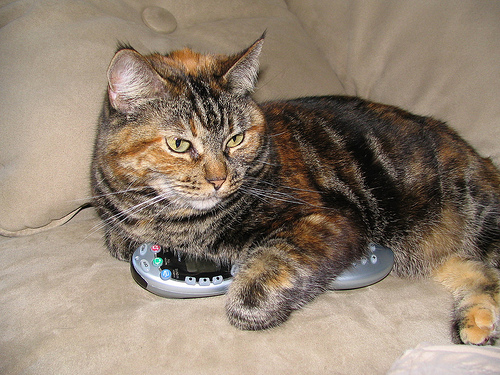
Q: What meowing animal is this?
A: Cat.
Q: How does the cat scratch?
A: Claws.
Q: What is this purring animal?
A: Cat.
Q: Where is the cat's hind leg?
A: Lower right corner.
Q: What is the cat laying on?
A: Remote control.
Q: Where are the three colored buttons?
A: Gray remote.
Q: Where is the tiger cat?
A: Sofa.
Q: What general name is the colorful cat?
A: Calico.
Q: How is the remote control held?
A: Cat's paw.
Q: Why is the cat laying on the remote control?
A: Likes it.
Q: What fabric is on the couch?
A: Creamy beige.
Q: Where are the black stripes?
A: Cat's torso.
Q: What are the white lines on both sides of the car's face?
A: Whiskers.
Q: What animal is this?
A: A cat.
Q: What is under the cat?
A: A remote control.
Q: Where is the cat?
A: On a couch.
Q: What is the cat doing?
A: Lying on the couch.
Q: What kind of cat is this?
A: Orange, black, and cream calico cat.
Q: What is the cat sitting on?
A: The remote.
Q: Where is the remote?
A: Under the cat's paw.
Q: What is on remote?
A: Cat's paw.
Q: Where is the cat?
A: On the sofa.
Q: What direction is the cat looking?
A: Over left shoulder.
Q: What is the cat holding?
A: Remote control.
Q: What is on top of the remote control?
A: Cat.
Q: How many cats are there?
A: One.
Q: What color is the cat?
A: Brown.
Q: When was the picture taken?
A: Day time.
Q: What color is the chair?
A: Tan.